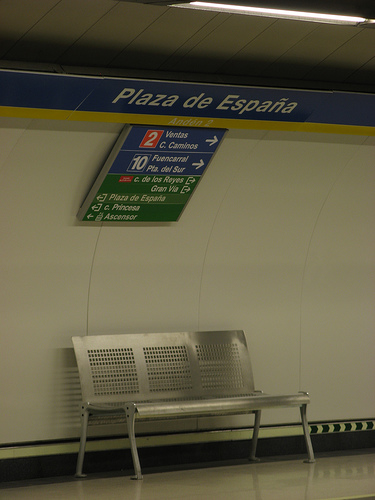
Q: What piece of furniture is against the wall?
A: A bench.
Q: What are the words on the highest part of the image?
A: Plaza de Espana.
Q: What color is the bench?
A: Silver.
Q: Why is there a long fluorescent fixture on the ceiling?
A: For light.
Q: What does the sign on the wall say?
A: Plaza de Espana.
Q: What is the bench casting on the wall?
A: A shadow.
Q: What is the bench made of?
A: Metal.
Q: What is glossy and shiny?
A: The floor.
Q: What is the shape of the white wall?
A: It is curved.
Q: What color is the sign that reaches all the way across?
A: Blue and yellow.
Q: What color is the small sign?
A: Blue and green.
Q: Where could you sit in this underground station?
A: On the metal bench.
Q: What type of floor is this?
A: Tile.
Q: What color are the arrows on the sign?
A: White.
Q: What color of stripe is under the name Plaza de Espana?
A: Yellow.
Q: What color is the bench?
A: Silver.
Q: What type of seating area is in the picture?
A: Bench.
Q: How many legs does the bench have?
A: 4.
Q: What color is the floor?
A: White.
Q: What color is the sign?
A: Green and blue.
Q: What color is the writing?
A: White.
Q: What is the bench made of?
A: Metal.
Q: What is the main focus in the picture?
A: A bench.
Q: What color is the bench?
A: Silver.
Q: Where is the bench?
A: An airport.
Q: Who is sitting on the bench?
A: No one.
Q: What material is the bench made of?
A: Metal.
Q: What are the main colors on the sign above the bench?
A: Green and blue.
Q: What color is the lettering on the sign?
A: White.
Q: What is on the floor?
A: Tile.